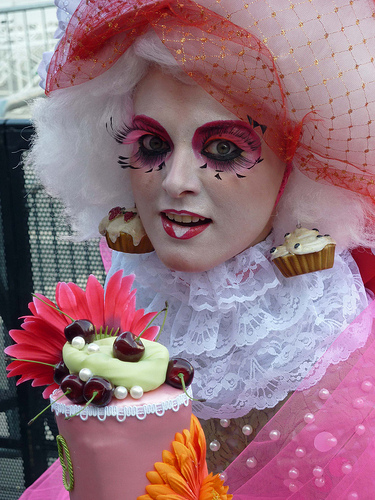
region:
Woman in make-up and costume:
[26, 32, 358, 334]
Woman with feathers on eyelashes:
[99, 101, 264, 198]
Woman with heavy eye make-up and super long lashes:
[94, 105, 295, 183]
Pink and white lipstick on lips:
[138, 195, 223, 251]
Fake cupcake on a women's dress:
[213, 80, 357, 331]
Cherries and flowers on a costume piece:
[19, 259, 217, 485]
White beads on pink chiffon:
[208, 333, 368, 491]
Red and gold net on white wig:
[0, 1, 371, 113]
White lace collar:
[201, 184, 263, 406]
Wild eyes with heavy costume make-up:
[87, 70, 285, 246]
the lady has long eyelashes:
[102, 107, 269, 183]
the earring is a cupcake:
[268, 216, 338, 278]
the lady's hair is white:
[19, 32, 370, 273]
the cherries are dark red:
[43, 315, 195, 405]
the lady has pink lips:
[151, 205, 213, 240]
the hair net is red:
[37, 1, 373, 199]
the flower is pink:
[4, 269, 163, 399]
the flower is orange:
[124, 415, 230, 499]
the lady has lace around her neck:
[100, 237, 372, 420]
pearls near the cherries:
[67, 332, 143, 402]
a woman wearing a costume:
[19, 2, 370, 497]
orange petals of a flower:
[135, 414, 230, 498]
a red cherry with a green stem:
[115, 310, 164, 363]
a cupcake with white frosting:
[269, 221, 335, 277]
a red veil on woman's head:
[44, 2, 374, 201]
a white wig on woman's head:
[22, 0, 373, 251]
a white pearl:
[129, 386, 144, 398]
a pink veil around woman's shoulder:
[20, 299, 372, 497]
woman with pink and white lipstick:
[160, 207, 210, 237]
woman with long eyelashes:
[102, 115, 169, 173]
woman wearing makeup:
[105, 62, 315, 273]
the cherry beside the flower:
[28, 290, 113, 348]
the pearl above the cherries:
[78, 369, 90, 378]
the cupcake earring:
[258, 219, 357, 273]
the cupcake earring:
[94, 203, 165, 265]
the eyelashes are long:
[94, 115, 152, 149]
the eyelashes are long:
[204, 119, 278, 159]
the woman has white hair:
[36, 48, 363, 275]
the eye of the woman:
[118, 122, 172, 160]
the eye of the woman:
[190, 131, 250, 166]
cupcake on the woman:
[270, 217, 345, 276]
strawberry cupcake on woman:
[97, 199, 146, 266]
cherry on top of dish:
[115, 327, 145, 362]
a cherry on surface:
[165, 349, 203, 411]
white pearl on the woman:
[235, 424, 254, 439]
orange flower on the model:
[141, 418, 218, 498]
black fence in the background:
[0, 174, 33, 497]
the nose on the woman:
[161, 145, 204, 203]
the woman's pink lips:
[162, 202, 219, 254]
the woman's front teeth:
[172, 212, 194, 224]